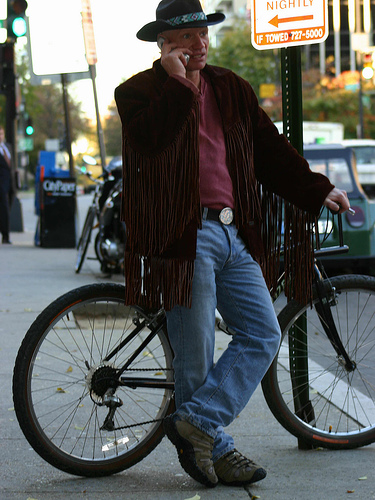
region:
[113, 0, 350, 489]
man in western attire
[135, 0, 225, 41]
black cowboy hat on man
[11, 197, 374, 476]
black bicycle behind man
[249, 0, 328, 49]
street sign behind man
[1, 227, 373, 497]
a sidewalk under the man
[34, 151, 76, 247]
newspaper boxes behind the man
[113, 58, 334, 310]
unique coat on man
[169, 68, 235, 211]
red shirt on man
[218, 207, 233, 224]
large belt buckle on man's waist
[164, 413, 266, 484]
brown shoes on man's feet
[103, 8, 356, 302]
man wearing a cowboy hat, coat and jeans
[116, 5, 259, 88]
man wearing a black cowboy hat with blue decorations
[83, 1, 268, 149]
a man with grey hair talking on a phone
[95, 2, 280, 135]
older man talking on a cell phone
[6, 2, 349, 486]
man leaning against a bike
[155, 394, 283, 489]
brown shoes with black soles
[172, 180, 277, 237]
black belt with round belt buckle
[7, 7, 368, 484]
man leaning on a bike on a sidewalk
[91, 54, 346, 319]
brown coat with brown tassles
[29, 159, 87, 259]
newspaper stand on a sidewalk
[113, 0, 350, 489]
A man on the phone.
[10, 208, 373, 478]
A bike in a rack.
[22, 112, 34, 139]
A traffic light on green.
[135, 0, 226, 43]
A black cowboy hat.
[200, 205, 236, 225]
A belt and buckle.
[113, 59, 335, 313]
A jacket with fringe.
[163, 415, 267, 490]
A pair of shoes.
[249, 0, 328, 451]
A sign on a pole.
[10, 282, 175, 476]
Back tire on a bike.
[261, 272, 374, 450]
Front tire on a bike.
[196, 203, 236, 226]
A black belt.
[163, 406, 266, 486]
A brown and black pair of hiking shoes.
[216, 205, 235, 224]
A silver belt buckle.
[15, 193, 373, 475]
A bicycle.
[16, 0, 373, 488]
A man leaning against a bicycle.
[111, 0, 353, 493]
A man talking on a cellphone.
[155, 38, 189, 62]
A silver cellphone.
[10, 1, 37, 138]
Traffic lights displaying green lights.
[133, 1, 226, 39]
A round black hat.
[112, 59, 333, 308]
A brown coat with long brown strings hanging from it.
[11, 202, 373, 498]
a small bike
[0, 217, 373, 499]
part of a sidewalk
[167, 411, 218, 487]
the shoe of a man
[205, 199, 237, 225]
a man's belt buckle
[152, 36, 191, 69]
a gray cellphone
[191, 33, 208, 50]
the nose of a man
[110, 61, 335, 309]
a man's brown coat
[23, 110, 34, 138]
a black street light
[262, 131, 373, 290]
part of a green vehicle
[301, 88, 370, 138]
part of a green tree